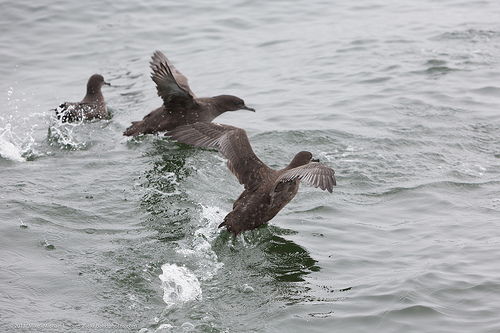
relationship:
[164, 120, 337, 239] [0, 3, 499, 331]
bird in water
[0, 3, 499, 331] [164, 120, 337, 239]
water behind bird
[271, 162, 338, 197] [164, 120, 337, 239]
wing of bird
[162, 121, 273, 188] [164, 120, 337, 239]
wing of bird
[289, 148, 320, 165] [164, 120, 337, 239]
head of bird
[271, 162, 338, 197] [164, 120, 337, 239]
wing on a bird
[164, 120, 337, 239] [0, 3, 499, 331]
bird swimming in water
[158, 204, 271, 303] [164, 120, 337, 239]
splash created by bird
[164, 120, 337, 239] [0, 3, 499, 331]
bird splashing in water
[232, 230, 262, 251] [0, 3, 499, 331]
feet in water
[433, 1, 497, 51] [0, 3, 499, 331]
part of a water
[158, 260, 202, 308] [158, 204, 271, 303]
part of a splash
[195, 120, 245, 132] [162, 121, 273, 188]
edge of a wing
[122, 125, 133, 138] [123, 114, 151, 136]
part of a tail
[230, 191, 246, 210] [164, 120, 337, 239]
edge of a bird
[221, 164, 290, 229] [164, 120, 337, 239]
back of a bird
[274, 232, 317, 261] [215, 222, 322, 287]
edge of a shadow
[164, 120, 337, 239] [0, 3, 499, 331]
bird above water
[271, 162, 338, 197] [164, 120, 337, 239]
wing of a bird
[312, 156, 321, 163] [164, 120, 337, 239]
beak of a bird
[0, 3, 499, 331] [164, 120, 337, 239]
water under bird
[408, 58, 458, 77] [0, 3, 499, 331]
ripples of water